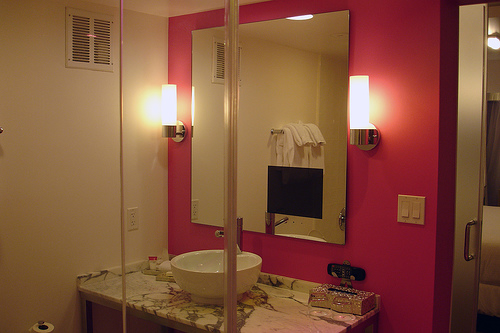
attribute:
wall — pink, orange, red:
[167, 2, 459, 331]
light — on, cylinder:
[160, 84, 187, 143]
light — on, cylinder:
[348, 74, 381, 152]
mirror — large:
[190, 9, 350, 245]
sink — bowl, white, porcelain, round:
[170, 247, 263, 305]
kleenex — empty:
[310, 281, 375, 316]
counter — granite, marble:
[76, 255, 381, 332]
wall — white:
[1, 1, 168, 332]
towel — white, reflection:
[275, 127, 295, 167]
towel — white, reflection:
[287, 123, 312, 169]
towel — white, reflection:
[303, 122, 326, 168]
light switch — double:
[397, 193, 426, 225]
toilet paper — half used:
[29, 320, 53, 333]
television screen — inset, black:
[266, 164, 323, 219]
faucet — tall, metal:
[215, 217, 243, 254]